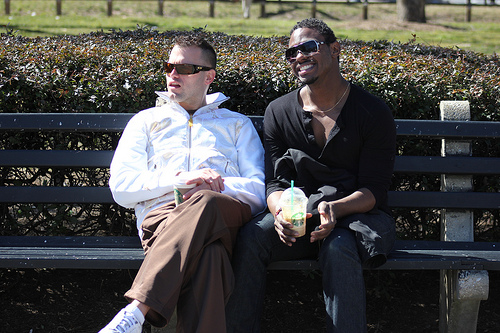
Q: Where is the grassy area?
A: Behind the bench.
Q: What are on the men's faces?
A: Sunglasses.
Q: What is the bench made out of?
A: Wood.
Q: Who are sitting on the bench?
A: Two men.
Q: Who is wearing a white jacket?
A: Man on the left.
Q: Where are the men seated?
A: On a bench.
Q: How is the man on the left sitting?
A: With legs crossed.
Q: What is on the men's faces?
A: Sunglasses.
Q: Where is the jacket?
A: On man's lap.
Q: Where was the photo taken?
A: Park.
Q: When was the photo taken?
A: Sunny day.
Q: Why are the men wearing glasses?
A: To protect eyes from sun.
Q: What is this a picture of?
A: Two people sitting on the bench.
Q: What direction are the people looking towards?
A: To the left.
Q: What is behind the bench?
A: Hedges.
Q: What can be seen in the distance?
A: A field.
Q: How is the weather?
A: Sunny.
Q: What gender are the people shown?
A: Male.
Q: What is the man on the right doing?
A: Smiling.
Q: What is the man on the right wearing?
A: A white jacket.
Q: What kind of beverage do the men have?
A: A starbucks beverage.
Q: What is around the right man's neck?
A: A silver necklace.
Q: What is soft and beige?
A: Pants.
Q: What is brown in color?
A: Pants.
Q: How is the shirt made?
A: Long sleeve.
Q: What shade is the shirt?
A: Black.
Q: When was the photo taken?
A: Daytime.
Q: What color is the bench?
A: Black.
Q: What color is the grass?
A: Green.